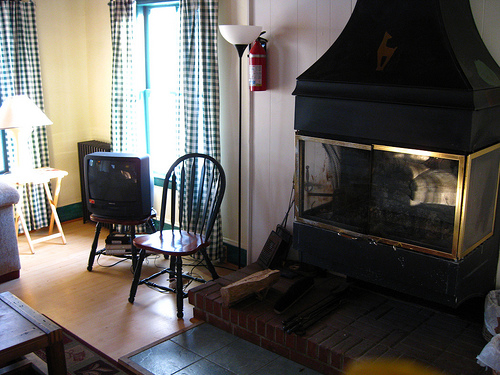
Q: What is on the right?
A: Fireplace.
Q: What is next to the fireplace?
A: Lamp.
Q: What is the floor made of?
A: Wood.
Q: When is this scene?
A: Daytime.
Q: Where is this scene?
A: Living room.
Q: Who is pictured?
A: No one.